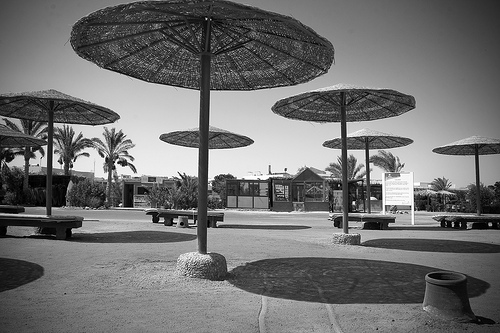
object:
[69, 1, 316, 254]
umbrella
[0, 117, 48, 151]
umbrella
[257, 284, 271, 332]
lines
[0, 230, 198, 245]
shadow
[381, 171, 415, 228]
sign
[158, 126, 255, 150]
umbrella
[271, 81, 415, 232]
umbrella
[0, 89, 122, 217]
umbrella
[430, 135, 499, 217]
umbrella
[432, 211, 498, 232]
bench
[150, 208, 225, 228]
bench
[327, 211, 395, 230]
bench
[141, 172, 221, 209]
bush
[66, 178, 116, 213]
trees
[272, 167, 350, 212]
buidings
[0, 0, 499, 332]
picture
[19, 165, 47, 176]
wall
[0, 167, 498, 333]
patio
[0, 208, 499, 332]
concrete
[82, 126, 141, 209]
palm tree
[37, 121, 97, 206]
palm tree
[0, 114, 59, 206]
palm tree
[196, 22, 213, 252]
pole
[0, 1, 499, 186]
blue sky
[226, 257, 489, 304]
shadow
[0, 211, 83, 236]
bench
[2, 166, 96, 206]
building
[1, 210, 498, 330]
area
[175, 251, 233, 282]
stand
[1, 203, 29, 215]
bench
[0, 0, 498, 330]
park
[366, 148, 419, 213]
tree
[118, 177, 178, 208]
building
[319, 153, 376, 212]
tree